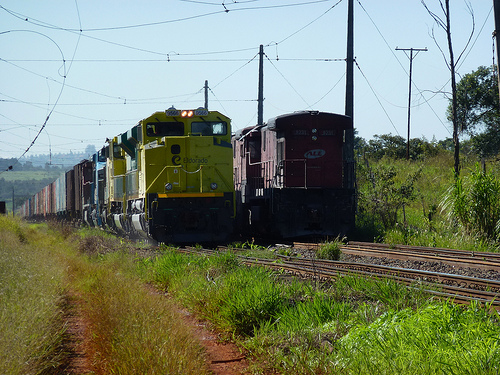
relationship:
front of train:
[144, 107, 235, 246] [28, 123, 248, 253]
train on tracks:
[56, 110, 228, 247] [259, 244, 422, 274]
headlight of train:
[160, 178, 177, 196] [13, 108, 239, 251]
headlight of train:
[202, 178, 244, 230] [56, 110, 412, 288]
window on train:
[143, 113, 230, 140] [13, 108, 239, 251]